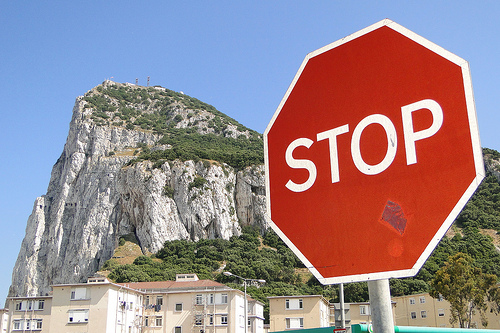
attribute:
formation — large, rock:
[62, 86, 240, 293]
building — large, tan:
[4, 258, 494, 331]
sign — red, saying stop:
[247, 17, 489, 290]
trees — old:
[138, 236, 172, 296]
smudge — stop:
[380, 198, 417, 259]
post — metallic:
[384, 266, 425, 330]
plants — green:
[228, 256, 262, 283]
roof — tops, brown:
[122, 274, 220, 293]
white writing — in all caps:
[280, 106, 494, 199]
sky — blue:
[196, 44, 273, 102]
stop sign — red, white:
[258, 12, 487, 289]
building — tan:
[0, 268, 265, 330]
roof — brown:
[110, 265, 234, 297]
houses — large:
[0, 263, 497, 331]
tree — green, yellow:
[420, 252, 497, 329]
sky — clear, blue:
[0, 2, 498, 308]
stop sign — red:
[200, 42, 481, 277]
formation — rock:
[48, 34, 259, 304]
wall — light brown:
[192, 227, 484, 317]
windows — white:
[51, 286, 209, 331]